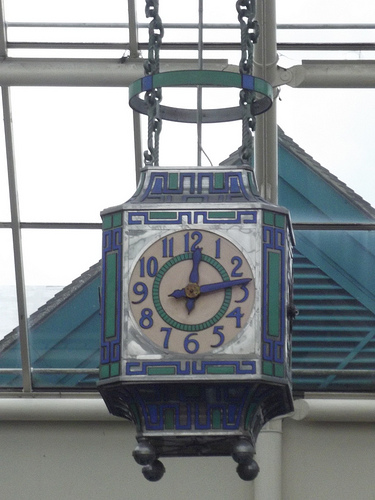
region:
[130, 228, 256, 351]
Gray and blue colored clock face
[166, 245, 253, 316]
Black and blue clock arms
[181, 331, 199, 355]
A small blue number six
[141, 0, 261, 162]
A pair of matching chains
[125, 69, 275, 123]
A gray and blue striped ring support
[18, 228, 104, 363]
Small square glass window piece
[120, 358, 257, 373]
Blue and gray Aztec design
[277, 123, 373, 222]
Top piece of roof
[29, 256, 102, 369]
Bottom piece of roof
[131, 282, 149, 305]
Curly blue number nine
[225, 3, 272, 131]
chain supporting a clock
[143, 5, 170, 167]
chain supporting a clock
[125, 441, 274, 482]
four balls on the clock's bottom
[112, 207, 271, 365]
the time is 12:13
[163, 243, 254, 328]
blue hands on clock face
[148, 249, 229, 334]
green circle on clock face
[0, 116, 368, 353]
peaked roof in background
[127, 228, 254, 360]
arabic numbers on clock face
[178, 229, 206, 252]
the number twelve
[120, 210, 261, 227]
decoration above the clock face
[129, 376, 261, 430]
blue and green deign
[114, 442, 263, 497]
four silver balls on bottom of object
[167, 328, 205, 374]
a blue number 6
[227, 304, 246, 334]
a blue number 4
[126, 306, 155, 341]
a blue number 8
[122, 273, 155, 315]
a blue number 9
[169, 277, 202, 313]
a gold flower in middle of clock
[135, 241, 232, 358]
blue clock hands with gold flower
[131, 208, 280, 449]
a large green and blue clock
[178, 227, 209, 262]
a blue number 12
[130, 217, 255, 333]
clock with blue numbers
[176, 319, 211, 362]
blue number on clock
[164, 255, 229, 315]
two hands on the clock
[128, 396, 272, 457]
bottom part of the clock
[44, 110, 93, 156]
sky above the house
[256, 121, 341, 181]
top of a structure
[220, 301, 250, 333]
the number 4 on the clock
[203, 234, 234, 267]
the number one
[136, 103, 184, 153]
chain holding the clock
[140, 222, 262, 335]
clock with little hand pointing at twelve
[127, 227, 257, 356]
the face of a clock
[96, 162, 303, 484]
a clock frame hanging from the ceiling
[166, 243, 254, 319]
the hands of a clock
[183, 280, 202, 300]
the middle of a clock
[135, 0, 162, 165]
a chain over the clock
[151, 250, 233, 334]
a green ring on the clock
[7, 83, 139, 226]
a window behind the clock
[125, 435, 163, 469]
a metal ball under the clock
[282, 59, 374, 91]
a gray metal beam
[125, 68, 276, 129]
a ring over the clock frame